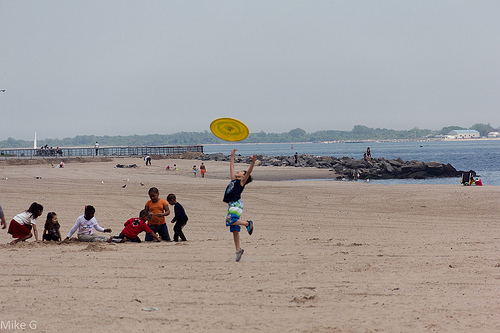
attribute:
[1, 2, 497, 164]
sky — overcast, gray, grey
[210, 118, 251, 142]
frisbee — large, yellow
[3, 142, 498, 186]
water — blue, calm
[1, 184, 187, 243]
people — playing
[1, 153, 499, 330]
sand — tan, rocky, sandy, beige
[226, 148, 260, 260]
person — playing, jumping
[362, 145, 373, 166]
person — sitting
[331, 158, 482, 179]
rocks — dark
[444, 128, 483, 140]
building — large, blue, white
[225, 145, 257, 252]
kid — jumping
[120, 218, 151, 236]
boy — little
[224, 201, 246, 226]
shorts — colorful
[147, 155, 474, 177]
expanse — large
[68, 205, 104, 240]
outfit — white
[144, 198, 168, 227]
t-shirt — orange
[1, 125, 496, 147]
tree line — long, green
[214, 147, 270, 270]
boy — young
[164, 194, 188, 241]
over — playing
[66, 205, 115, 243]
child — playing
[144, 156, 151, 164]
adult — kneeling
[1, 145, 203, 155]
pier — wooden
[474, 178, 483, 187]
cooler — red, white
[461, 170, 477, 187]
person — sitting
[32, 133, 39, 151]
boat — white